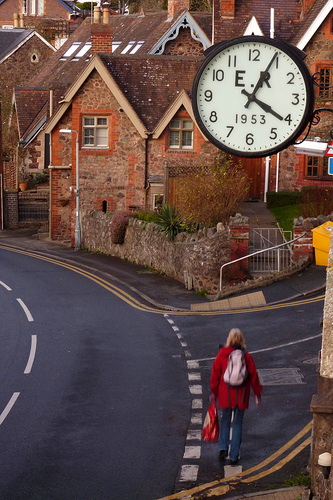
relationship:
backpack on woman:
[222, 349, 247, 385] [204, 327, 263, 463]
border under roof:
[157, 29, 202, 53] [76, 13, 208, 52]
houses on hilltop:
[16, 2, 315, 273] [6, 191, 328, 364]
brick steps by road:
[18, 190, 48, 228] [0, 243, 327, 499]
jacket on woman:
[209, 345, 259, 411] [204, 327, 263, 463]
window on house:
[82, 113, 111, 146] [36, 29, 221, 266]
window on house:
[167, 118, 193, 149] [42, 50, 263, 246]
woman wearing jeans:
[204, 327, 263, 463] [212, 397, 247, 466]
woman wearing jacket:
[204, 327, 263, 463] [204, 343, 265, 404]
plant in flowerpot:
[14, 170, 32, 182] [17, 184, 27, 192]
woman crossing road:
[209, 329, 263, 466] [0, 243, 327, 499]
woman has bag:
[209, 329, 263, 466] [202, 398, 220, 443]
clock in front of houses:
[187, 35, 317, 157] [6, 22, 192, 250]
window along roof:
[82, 114, 109, 148] [3, 10, 188, 113]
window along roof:
[169, 118, 194, 148] [3, 10, 188, 113]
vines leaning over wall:
[105, 204, 127, 243] [76, 198, 233, 293]